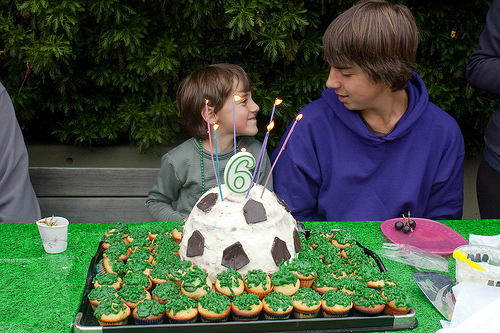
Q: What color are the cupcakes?
A: Green and brown.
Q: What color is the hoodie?
A: Purple.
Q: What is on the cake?
A: Candles.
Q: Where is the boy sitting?
A: Behind the cake.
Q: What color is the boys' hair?
A: Brown.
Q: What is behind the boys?
A: A green plant.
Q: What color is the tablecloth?
A: Green.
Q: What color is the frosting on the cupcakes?
A: Green.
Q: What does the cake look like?
A: A soccer ball.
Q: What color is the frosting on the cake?
A: White.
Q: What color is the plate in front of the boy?
A: Pink.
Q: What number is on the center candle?
A: 6.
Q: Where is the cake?
A: On the table.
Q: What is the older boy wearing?
A: A hoodie.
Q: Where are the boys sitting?
A: On the bench.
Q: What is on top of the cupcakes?
A: Green frosting.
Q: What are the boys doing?
A: Looking at each other.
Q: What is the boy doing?
A: Looking at the younger boy.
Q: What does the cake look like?
A: A soccer ball.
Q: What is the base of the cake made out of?
A: Cupcakes.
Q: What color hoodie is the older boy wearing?
A: Purple.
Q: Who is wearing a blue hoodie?
A: A boy.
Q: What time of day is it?
A: Daytime.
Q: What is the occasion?
A: Birthday.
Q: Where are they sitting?
A: Picnic table.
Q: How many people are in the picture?
A: Three.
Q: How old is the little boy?
A: Six.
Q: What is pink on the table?
A: Plate.